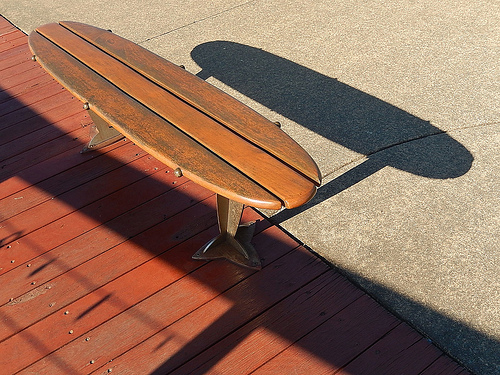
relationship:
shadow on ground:
[214, 46, 455, 170] [92, 15, 490, 270]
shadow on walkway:
[214, 46, 455, 170] [203, 10, 482, 114]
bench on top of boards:
[42, 26, 317, 217] [12, 175, 111, 258]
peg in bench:
[165, 164, 194, 190] [42, 26, 317, 217]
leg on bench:
[200, 215, 266, 269] [42, 26, 317, 217]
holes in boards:
[26, 279, 87, 338] [12, 175, 111, 258]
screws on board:
[73, 98, 96, 114] [41, 44, 244, 196]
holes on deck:
[26, 279, 87, 338] [16, 203, 160, 370]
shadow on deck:
[12, 237, 205, 374] [101, 71, 185, 152]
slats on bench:
[83, 51, 168, 122] [42, 26, 317, 217]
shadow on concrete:
[214, 46, 455, 170] [203, 10, 482, 114]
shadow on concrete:
[214, 46, 455, 170] [248, 16, 500, 204]